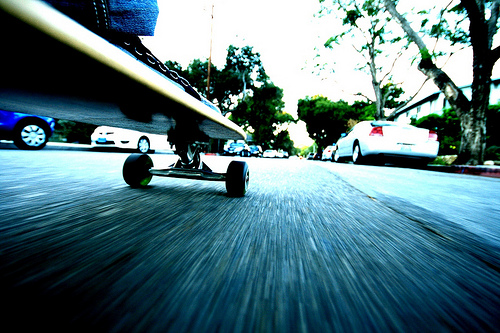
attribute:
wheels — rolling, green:
[120, 151, 253, 199]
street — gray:
[1, 151, 499, 332]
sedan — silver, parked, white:
[332, 119, 443, 166]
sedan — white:
[88, 125, 173, 155]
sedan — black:
[222, 140, 251, 157]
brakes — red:
[369, 124, 440, 141]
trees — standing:
[239, 84, 376, 159]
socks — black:
[100, 34, 200, 103]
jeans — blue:
[39, 0, 160, 39]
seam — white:
[91, 0, 113, 32]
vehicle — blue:
[0, 104, 57, 151]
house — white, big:
[391, 79, 498, 124]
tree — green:
[229, 82, 296, 154]